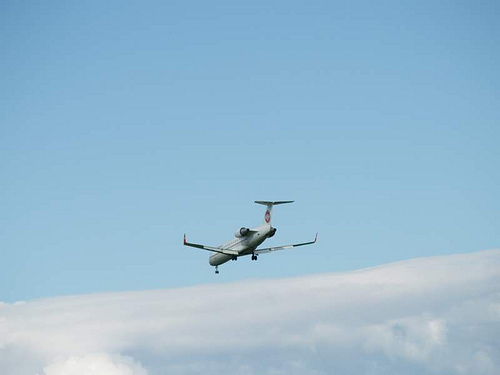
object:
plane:
[183, 200, 320, 273]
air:
[249, 0, 498, 145]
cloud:
[1, 249, 500, 375]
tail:
[272, 199, 294, 206]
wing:
[183, 233, 240, 256]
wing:
[254, 232, 319, 254]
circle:
[264, 210, 270, 223]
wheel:
[252, 255, 255, 259]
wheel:
[254, 256, 258, 261]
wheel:
[232, 255, 235, 261]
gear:
[215, 270, 220, 274]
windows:
[235, 240, 236, 243]